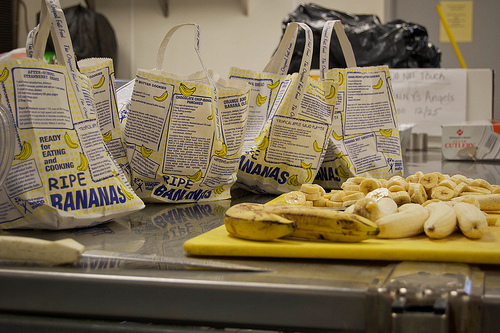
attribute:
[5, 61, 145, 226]
bag — paper, black, white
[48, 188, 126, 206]
writing — blue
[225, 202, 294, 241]
banana — yellow, bruised, not peeled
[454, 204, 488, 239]
banana — peeled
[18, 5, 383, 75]
wall — white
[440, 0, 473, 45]
notice — yellow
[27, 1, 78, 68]
handle — wood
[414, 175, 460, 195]
banana — sliced, stacked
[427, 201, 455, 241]
banana — peeled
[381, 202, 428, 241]
banana — peeled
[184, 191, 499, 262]
cutting board — yellow, plastic, flat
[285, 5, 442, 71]
bag — plastic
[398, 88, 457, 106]
writing — black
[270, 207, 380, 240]
banana — yellow